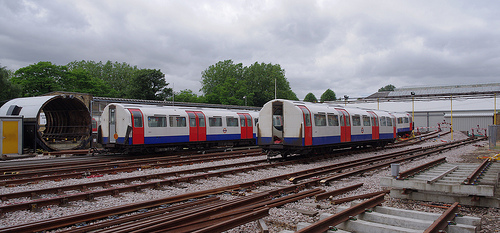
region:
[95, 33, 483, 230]
A train is on the railroad tracks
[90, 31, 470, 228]
Two trains are parked close together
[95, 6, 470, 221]
A train is waiting for passengers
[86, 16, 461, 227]
The trains are owned by the railroad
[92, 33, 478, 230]
The trains have big powerful locomotives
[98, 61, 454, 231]
The trains are running on time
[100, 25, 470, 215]
The trains are transporting commuters home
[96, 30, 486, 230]
The trains are carrying happy vacationers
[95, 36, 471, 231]
The trains are close to some trees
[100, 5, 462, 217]
The trains are operating very safely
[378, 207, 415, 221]
wood timber used on a railroad track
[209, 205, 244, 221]
metal rails used for train tracks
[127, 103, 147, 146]
a single door on a train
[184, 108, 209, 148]
a double door used on a train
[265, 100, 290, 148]
the front door of a train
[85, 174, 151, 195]
rail road tracks on gravel and wood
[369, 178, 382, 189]
gravel used as the base for train tracks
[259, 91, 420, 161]
an empty train at a station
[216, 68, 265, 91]
green leaves on trees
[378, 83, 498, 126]
large buildings at a railroad station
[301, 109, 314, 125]
window on a train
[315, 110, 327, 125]
window on a train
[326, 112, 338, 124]
window on a train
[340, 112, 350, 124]
window on a train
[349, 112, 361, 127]
window on a train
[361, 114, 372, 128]
window on a train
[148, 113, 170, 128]
window on a train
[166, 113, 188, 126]
window on a train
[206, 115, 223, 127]
window on a train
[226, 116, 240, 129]
window on a train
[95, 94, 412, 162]
two trains on tracks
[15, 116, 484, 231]
train tracks on the ground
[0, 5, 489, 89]
rain clouds in the sky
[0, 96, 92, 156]
large round industrial object on the ground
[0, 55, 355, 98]
large trees in the background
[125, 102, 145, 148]
red door on the train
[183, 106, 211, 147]
red double doors on the train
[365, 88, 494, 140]
buildings in the background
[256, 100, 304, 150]
back of the train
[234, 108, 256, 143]
double red doors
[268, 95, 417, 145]
red, white, and blue train cars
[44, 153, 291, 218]
train tracks side by side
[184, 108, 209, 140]
red doors on a train car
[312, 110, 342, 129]
windows on the side of a train car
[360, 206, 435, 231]
cement railroad ties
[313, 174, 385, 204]
train rails laying in the gravel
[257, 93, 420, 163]
trains cars on a track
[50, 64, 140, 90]
trees with green leaves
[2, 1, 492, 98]
a grey overcast sky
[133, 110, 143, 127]
a window in a train car door